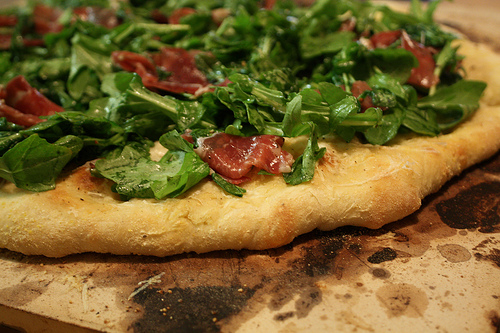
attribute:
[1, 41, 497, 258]
crust — yellow, brown, toasted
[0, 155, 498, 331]
table — brown, greasy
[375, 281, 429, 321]
grease stain — round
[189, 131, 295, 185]
meat — dark red, brown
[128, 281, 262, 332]
spot — black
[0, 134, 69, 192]
spinach — green